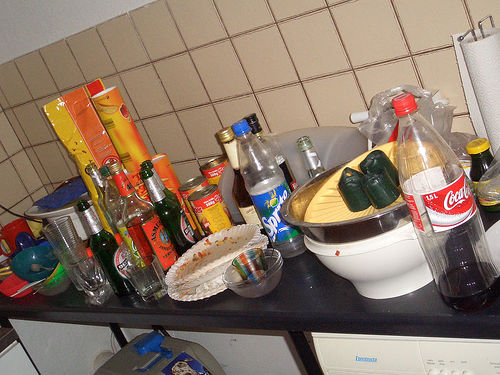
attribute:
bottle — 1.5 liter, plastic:
[393, 94, 500, 307]